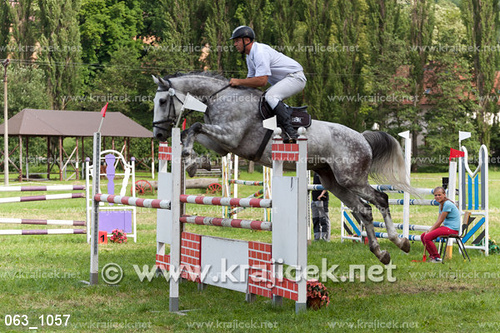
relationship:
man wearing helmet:
[226, 21, 313, 143] [228, 22, 257, 44]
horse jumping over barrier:
[150, 69, 425, 264] [89, 125, 312, 313]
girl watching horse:
[423, 172, 497, 277] [138, 72, 496, 240]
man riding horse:
[227, 25, 307, 145] [144, 67, 411, 264]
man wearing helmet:
[227, 25, 307, 145] [225, 24, 255, 49]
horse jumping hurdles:
[147, 60, 417, 212] [79, 92, 376, 296]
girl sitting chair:
[420, 186, 462, 264] [438, 211, 472, 266]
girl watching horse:
[420, 186, 462, 264] [144, 67, 411, 264]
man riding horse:
[226, 21, 313, 143] [144, 67, 411, 264]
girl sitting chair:
[420, 186, 462, 264] [443, 211, 473, 268]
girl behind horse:
[420, 186, 462, 264] [144, 67, 411, 264]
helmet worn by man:
[226, 22, 268, 44] [227, 25, 307, 145]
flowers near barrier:
[308, 282, 330, 311] [72, 122, 312, 316]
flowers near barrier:
[110, 223, 125, 241] [2, 147, 97, 262]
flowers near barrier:
[308, 282, 330, 311] [372, 120, 492, 259]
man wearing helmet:
[227, 25, 307, 145] [233, 19, 250, 44]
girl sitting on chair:
[420, 186, 462, 264] [438, 211, 472, 266]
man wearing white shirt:
[226, 21, 313, 143] [240, 39, 302, 79]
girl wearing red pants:
[420, 186, 462, 264] [419, 227, 458, 257]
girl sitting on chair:
[420, 186, 462, 264] [439, 207, 473, 261]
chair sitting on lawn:
[439, 207, 473, 261] [0, 177, 496, 330]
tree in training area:
[0, 0, 500, 173] [1, 80, 498, 332]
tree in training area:
[77, 0, 149, 166] [1, 80, 498, 332]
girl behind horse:
[420, 186, 462, 264] [133, 58, 426, 262]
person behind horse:
[302, 167, 333, 250] [133, 58, 426, 262]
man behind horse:
[227, 25, 307, 145] [133, 58, 426, 262]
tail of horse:
[358, 120, 418, 204] [144, 67, 411, 264]